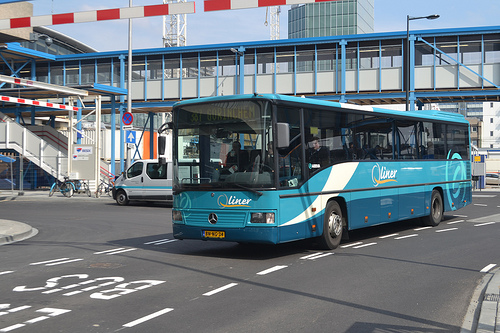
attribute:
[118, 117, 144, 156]
sign — blue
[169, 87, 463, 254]
bus — side, blue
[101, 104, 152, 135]
sign — blue 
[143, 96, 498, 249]
blue bus — blue 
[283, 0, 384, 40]
building — tall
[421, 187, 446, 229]
back tire — back 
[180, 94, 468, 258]
bus — blue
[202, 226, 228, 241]
license plate — yellow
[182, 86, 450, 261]
bus — blue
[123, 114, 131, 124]
lines — red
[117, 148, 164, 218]
van — white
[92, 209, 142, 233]
road — side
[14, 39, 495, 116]
bridge — blue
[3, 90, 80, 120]
sign — red, white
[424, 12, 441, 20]
light — Part, street 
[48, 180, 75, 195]
bicycle — blue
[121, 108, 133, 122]
circle — blue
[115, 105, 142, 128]
sign — blue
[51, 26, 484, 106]
walkway — elevated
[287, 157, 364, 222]
stripe — white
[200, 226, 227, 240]
plate — yellow license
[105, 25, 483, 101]
walkway — blue 